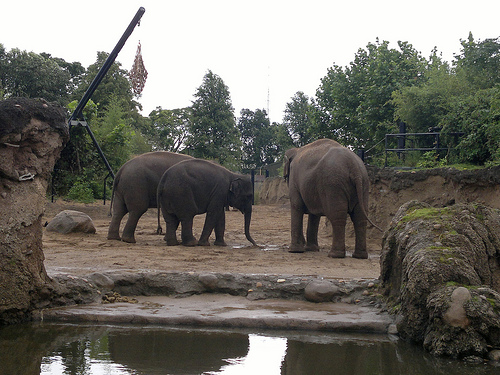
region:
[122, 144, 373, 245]
brown elephants near water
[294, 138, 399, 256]
elephant has long tail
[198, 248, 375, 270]
ground is dry and brown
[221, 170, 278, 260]
elephant has brown trunk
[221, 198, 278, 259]
elephant has long trunk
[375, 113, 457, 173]
black fence above elephants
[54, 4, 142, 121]
black pole above elephants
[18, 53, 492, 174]
green trees behind fence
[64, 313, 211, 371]
dark water in front of elephants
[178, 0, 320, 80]
sky is grey and cloudy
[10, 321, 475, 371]
WATER IS BROWN IN COLOR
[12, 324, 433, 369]
REFLECTIONS ARE IN THE WATER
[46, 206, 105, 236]
SINGLE BOULDER IS ON THE GROUND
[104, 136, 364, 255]
THREE ELEPHANTS ARE IN THE AREA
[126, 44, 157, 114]
FLAG IS HANGING FROM THE POLE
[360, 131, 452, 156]
METAL FENCE IS ON THE LEDGE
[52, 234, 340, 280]
GROUND IS MUDDY BROWN IN COLOR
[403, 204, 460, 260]
MOSS IS GROWING ON THE DIRT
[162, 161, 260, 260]
ELEPHANT IN MIDDLE IS THE SMALLEST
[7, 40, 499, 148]
GREEN FOLIAGE IS IN THE BACKGROUND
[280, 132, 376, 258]
An elephant standing around.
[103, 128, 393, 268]
elephants in the pen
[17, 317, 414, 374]
water beside the large stone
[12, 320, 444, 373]
the water is calm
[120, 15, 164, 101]
net hanging from the winch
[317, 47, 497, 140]
trees with green leaves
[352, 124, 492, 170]
black railing above the pen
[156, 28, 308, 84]
the sky is gray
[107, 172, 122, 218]
tail of the elephant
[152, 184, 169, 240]
tail of the elephant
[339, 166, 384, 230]
tail of the elephant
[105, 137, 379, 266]
elephants at the watering hole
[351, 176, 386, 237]
elephants rope like tail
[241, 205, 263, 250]
trunk on an elephant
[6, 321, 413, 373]
water for the elephants to drink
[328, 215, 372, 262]
elephants hind legs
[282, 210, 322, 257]
elephants front legs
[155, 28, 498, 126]
trees near the elephants area in the zoo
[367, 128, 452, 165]
fence to keep observers away from the elephants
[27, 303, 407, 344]
step leading into the elephants water area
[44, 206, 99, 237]
rock in the elephant area in the zoo